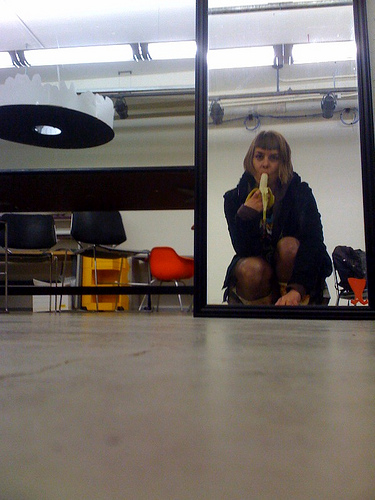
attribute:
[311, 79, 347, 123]
spotlight — black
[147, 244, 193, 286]
chair — red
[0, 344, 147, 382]
crack — dark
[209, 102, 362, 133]
wires — blue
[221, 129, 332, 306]
woman — eating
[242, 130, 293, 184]
hair — blonde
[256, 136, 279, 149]
bangs — short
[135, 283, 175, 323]
legs — silver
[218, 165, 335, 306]
coat — black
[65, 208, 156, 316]
chair — black